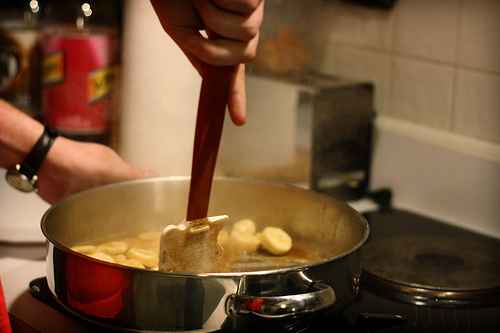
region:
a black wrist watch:
[6, 126, 62, 194]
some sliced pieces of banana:
[58, 215, 285, 275]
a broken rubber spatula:
[158, 17, 244, 276]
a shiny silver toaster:
[176, 57, 371, 193]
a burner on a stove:
[343, 237, 498, 304]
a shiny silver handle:
[219, 266, 339, 331]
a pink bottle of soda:
[36, 0, 111, 142]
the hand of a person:
[147, 1, 253, 128]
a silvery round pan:
[42, 156, 370, 323]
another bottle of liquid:
[0, 0, 42, 115]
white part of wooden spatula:
[164, 210, 240, 258]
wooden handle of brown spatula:
[176, 62, 275, 193]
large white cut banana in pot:
[262, 222, 294, 254]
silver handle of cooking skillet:
[225, 281, 326, 312]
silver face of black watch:
[5, 160, 45, 191]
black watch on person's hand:
[12, 125, 62, 191]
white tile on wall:
[377, 26, 477, 86]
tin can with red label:
[35, 20, 125, 130]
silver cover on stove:
[367, 229, 499, 296]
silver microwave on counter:
[227, 65, 398, 172]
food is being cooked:
[1, 152, 376, 324]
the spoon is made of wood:
[123, 14, 328, 273]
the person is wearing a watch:
[16, 105, 105, 239]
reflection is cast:
[60, 180, 226, 326]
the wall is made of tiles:
[405, 20, 458, 100]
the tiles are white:
[406, 43, 465, 109]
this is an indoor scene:
[22, 7, 441, 306]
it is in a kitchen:
[2, 6, 420, 329]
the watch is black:
[5, 107, 107, 237]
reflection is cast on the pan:
[135, 233, 269, 309]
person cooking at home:
[4, 5, 472, 317]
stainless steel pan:
[20, 86, 418, 326]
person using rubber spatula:
[16, 9, 414, 323]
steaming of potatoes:
[30, 80, 427, 332]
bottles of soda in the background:
[2, 1, 487, 331]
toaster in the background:
[141, 31, 396, 243]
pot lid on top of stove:
[367, 196, 497, 328]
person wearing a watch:
[8, 95, 113, 217]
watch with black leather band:
[0, 99, 110, 208]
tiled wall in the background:
[299, 6, 498, 128]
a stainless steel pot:
[35, 151, 386, 318]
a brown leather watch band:
[11, 117, 72, 188]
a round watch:
[3, 159, 55, 194]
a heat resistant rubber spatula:
[159, 38, 234, 280]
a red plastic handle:
[188, 37, 243, 229]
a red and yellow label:
[21, 2, 134, 150]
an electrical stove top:
[358, 208, 498, 321]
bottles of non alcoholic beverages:
[0, 2, 139, 164]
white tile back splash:
[308, 5, 498, 140]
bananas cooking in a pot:
[56, 210, 304, 268]